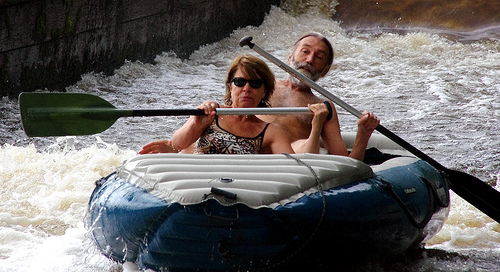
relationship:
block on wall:
[3, 0, 273, 99] [17, 10, 284, 100]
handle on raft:
[202, 185, 242, 207] [82, 127, 452, 269]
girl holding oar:
[175, 55, 327, 159] [18, 87, 335, 136]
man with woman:
[265, 15, 396, 208] [186, 45, 291, 193]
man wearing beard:
[253, 31, 381, 162] [289, 55, 320, 85]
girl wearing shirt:
[171, 53, 329, 154] [206, 120, 267, 147]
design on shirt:
[199, 130, 217, 148] [206, 120, 267, 147]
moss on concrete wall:
[39, 19, 59, 58] [1, 1, 111, 70]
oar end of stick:
[18, 92, 333, 137] [119, 107, 333, 117]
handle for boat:
[202, 187, 237, 200] [101, 112, 458, 264]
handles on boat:
[380, 168, 470, 223] [48, 100, 458, 270]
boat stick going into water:
[238, 35, 500, 224] [6, 12, 497, 270]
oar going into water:
[18, 92, 333, 137] [6, 12, 497, 270]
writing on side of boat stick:
[274, 64, 317, 88] [237, 27, 495, 216]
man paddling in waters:
[253, 31, 381, 162] [1, 11, 481, 270]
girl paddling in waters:
[171, 53, 329, 154] [1, 11, 481, 270]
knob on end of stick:
[232, 30, 263, 58] [238, 41, 459, 182]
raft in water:
[81, 145, 455, 270] [6, 12, 497, 270]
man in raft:
[253, 31, 381, 162] [79, 108, 456, 270]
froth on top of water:
[0, 130, 115, 222] [432, 73, 497, 141]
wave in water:
[385, 40, 467, 102] [344, 41, 495, 146]